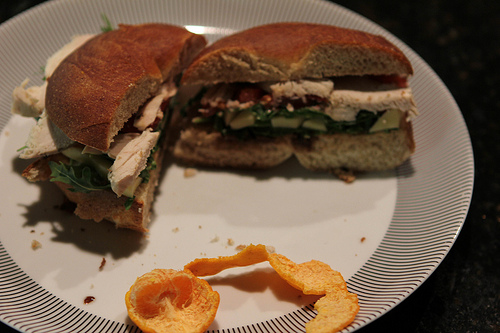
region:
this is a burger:
[181, 33, 421, 168]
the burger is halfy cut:
[201, 32, 410, 170]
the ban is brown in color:
[97, 44, 147, 85]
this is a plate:
[370, 175, 443, 237]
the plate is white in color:
[307, 205, 369, 240]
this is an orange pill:
[156, 276, 188, 316]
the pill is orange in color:
[161, 282, 192, 326]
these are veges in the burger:
[283, 111, 333, 135]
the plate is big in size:
[392, 190, 443, 240]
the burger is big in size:
[236, 44, 399, 131]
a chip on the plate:
[265, 237, 360, 331]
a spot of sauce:
[81, 293, 98, 306]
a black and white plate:
[0, 0, 478, 332]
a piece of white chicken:
[101, 127, 165, 197]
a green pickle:
[366, 107, 406, 134]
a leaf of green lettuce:
[43, 152, 117, 194]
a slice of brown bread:
[181, 20, 417, 88]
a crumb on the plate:
[28, 234, 46, 254]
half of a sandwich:
[166, 21, 428, 180]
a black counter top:
[0, 1, 497, 331]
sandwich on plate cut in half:
[0, 10, 425, 227]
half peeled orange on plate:
[115, 227, 381, 328]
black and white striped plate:
[317, 175, 485, 330]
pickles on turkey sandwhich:
[168, 12, 429, 187]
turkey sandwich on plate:
[28, 12, 453, 255]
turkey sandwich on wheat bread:
[267, 15, 408, 164]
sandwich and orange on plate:
[34, 3, 418, 330]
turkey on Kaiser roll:
[6, 16, 182, 241]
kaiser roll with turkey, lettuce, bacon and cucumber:
[46, 14, 493, 242]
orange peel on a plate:
[217, 219, 409, 330]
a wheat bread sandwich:
[56, 24, 410, 214]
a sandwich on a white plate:
[16, 13, 462, 226]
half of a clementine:
[136, 272, 194, 311]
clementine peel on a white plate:
[197, 232, 363, 331]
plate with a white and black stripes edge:
[386, 194, 484, 286]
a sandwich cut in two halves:
[42, 24, 429, 220]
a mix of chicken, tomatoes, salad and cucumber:
[181, 82, 422, 130]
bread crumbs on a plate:
[167, 202, 240, 247]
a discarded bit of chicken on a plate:
[11, 57, 46, 123]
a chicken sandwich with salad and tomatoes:
[58, 19, 410, 205]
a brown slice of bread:
[40, 14, 206, 151]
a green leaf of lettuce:
[43, 151, 145, 210]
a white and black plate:
[0, 0, 481, 331]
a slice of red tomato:
[233, 83, 268, 107]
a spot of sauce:
[80, 284, 102, 309]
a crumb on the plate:
[23, 235, 44, 248]